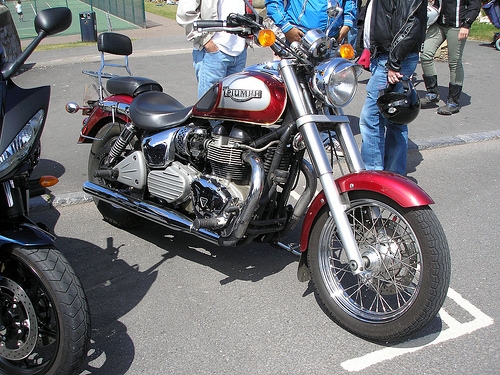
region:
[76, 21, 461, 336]
A red motorcycle in daylight.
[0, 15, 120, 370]
Another motorcycle parked next to the red motorcycle.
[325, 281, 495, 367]
White lines painted on the cement.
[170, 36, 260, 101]
A man wearing a pair of jeans.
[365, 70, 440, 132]
A man holding a black helmet.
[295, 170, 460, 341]
The front wheel of the red motorcycle.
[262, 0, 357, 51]
A person wearing a blue jacket.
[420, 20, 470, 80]
A person wearing green pants.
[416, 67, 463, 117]
A person wearing boots.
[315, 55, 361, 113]
A headlight on the motorcycle.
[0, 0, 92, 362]
a black motorcycle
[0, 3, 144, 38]
a chain link fence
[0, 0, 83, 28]
a tennis court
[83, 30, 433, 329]
a red motorcycle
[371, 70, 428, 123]
a black motorcycle helmet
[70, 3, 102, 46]
a trash can next to the tennis court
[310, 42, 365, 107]
headlight on the motorcycle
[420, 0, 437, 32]
a white motorcycle helmet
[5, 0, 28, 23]
a person playing tennis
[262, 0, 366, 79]
a man in a blue sweat shirt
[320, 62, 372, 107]
This motorcycle has a large front light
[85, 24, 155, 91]
There is a seat on this motorcycle for a passenger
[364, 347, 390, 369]
There is a white line here that tells one where to park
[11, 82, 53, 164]
This motorcycle has a sporty stile with black around the headlight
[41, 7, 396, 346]
This event might be a small motorcycle rally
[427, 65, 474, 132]
This person is wearing black boots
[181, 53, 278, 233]
There is a large engine on this motorcycle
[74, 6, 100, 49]
There is a trash can that is in the background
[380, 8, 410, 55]
This man is wearing a black leather jacket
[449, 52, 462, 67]
This person is wearing light-colored jeans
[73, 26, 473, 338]
A parked motorcycle.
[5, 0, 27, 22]
A person playing tennis.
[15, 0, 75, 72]
A side mirror.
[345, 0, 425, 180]
The man is holding a helmet.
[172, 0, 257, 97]
The man has his hands in his pockets.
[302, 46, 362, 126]
The motorcycle's headlight.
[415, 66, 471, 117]
Th person is wearing black boots.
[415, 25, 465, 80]
The person is wearing greenish-gray pants.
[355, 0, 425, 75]
A black leather jacket.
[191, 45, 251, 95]
Blue jeans.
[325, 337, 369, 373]
white paint on gray asphalt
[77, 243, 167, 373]
the shadow of a motorcycle on a parking lot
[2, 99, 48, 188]
the front headlight of a black motorcycle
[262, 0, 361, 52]
the blue jacket of a man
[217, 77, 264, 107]
the logo on the side of a motorcycle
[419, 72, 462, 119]
a pair of black motorcycle boots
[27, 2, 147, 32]
a green fence around a tennis court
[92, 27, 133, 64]
a black back rest on a motorcycle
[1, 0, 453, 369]
two motorcycles in a parking lot